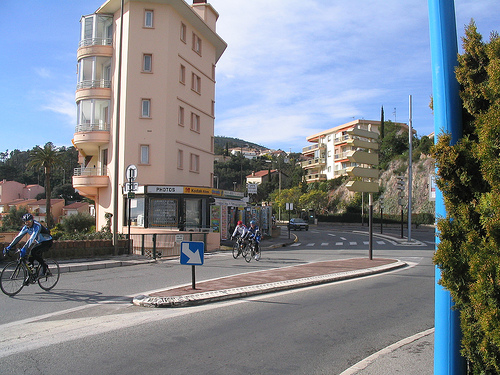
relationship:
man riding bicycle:
[3, 213, 53, 274] [0, 248, 60, 296]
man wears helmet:
[245, 216, 266, 249] [250, 220, 257, 227]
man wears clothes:
[245, 216, 266, 249] [247, 225, 259, 244]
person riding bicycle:
[232, 220, 249, 240] [233, 237, 246, 259]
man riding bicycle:
[243, 220, 261, 258] [245, 238, 262, 263]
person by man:
[232, 220, 249, 240] [243, 220, 261, 258]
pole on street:
[429, 0, 480, 372] [2, 217, 435, 370]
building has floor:
[71, 2, 233, 253] [69, 144, 214, 192]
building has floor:
[71, 2, 233, 253] [71, 96, 216, 149]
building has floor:
[71, 2, 233, 253] [74, 2, 219, 62]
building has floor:
[71, 2, 233, 253] [73, 56, 223, 100]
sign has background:
[180, 242, 205, 265] [180, 246, 201, 262]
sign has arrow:
[180, 242, 205, 265] [183, 244, 203, 263]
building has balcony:
[71, 2, 233, 253] [78, 13, 119, 61]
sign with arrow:
[180, 242, 205, 265] [183, 244, 203, 263]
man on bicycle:
[3, 213, 53, 274] [2, 248, 64, 296]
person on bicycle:
[232, 220, 249, 240] [233, 236, 244, 255]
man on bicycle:
[243, 220, 261, 258] [243, 241, 263, 261]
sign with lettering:
[149, 187, 184, 191] [155, 186, 177, 191]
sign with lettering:
[184, 183, 215, 198] [188, 186, 212, 196]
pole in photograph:
[429, 0, 480, 372] [10, 2, 500, 369]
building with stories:
[71, 2, 233, 253] [73, 12, 120, 188]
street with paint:
[2, 217, 435, 370] [4, 223, 411, 357]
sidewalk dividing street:
[135, 247, 405, 314] [2, 217, 435, 370]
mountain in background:
[211, 133, 299, 189] [180, 246, 201, 262]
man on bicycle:
[245, 216, 266, 249] [245, 238, 262, 263]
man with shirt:
[4, 204, 59, 283] [8, 220, 58, 254]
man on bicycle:
[4, 204, 59, 283] [0, 248, 60, 296]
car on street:
[285, 214, 310, 230] [0, 227, 436, 370]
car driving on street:
[285, 214, 310, 230] [0, 227, 436, 370]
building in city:
[71, 2, 233, 253] [5, 3, 498, 368]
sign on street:
[180, 242, 204, 265] [0, 227, 436, 370]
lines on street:
[3, 209, 433, 356] [0, 227, 436, 370]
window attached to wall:
[173, 106, 191, 128] [130, 1, 219, 185]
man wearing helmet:
[3, 213, 53, 274] [22, 210, 35, 222]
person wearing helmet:
[232, 220, 249, 240] [237, 217, 244, 226]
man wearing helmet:
[243, 220, 261, 258] [250, 220, 257, 227]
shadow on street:
[28, 253, 308, 311] [0, 227, 436, 370]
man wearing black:
[4, 204, 59, 283] [31, 226, 53, 241]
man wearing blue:
[4, 204, 59, 283] [9, 223, 51, 261]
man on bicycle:
[4, 204, 59, 283] [2, 248, 64, 296]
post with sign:
[118, 162, 143, 256] [125, 164, 138, 184]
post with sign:
[118, 162, 143, 256] [124, 180, 142, 197]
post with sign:
[118, 162, 143, 256] [125, 191, 139, 201]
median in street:
[131, 246, 402, 316] [2, 217, 435, 370]